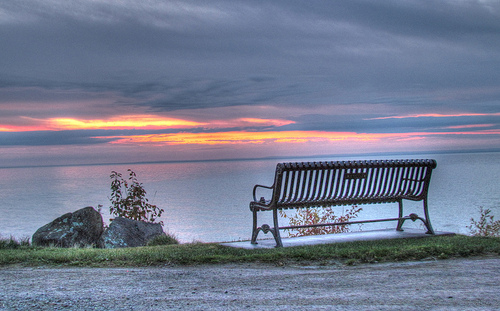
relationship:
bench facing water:
[251, 159, 438, 250] [2, 151, 497, 243]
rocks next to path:
[32, 206, 164, 251] [2, 253, 499, 310]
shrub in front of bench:
[279, 205, 364, 239] [251, 159, 438, 250]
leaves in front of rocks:
[95, 168, 165, 227] [32, 206, 164, 251]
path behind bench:
[2, 253, 499, 310] [251, 159, 438, 250]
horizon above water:
[1, 148, 499, 169] [2, 151, 497, 243]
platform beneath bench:
[220, 228, 455, 251] [251, 159, 438, 250]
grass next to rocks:
[3, 234, 180, 269] [32, 206, 164, 251]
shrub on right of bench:
[465, 207, 499, 237] [251, 159, 438, 250]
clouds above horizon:
[3, 2, 493, 146] [1, 148, 499, 169]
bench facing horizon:
[251, 159, 438, 250] [1, 148, 499, 169]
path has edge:
[2, 253, 499, 310] [2, 247, 499, 265]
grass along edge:
[3, 236, 500, 264] [2, 247, 499, 265]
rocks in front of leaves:
[32, 206, 164, 251] [95, 168, 165, 227]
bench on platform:
[251, 159, 438, 250] [220, 228, 455, 251]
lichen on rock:
[103, 223, 130, 249] [97, 216, 167, 250]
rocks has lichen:
[32, 206, 164, 251] [44, 217, 129, 251]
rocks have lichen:
[32, 206, 164, 251] [44, 217, 129, 251]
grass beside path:
[3, 234, 180, 269] [2, 253, 499, 310]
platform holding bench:
[220, 228, 455, 251] [251, 159, 438, 250]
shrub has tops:
[279, 205, 364, 239] [108, 168, 138, 182]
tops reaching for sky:
[108, 168, 138, 182] [0, 2, 497, 142]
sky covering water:
[0, 2, 497, 142] [2, 151, 497, 243]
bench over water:
[251, 159, 438, 250] [2, 151, 497, 243]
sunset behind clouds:
[0, 112, 498, 149] [3, 2, 493, 146]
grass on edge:
[3, 234, 180, 269] [2, 247, 499, 265]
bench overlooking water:
[251, 159, 438, 250] [2, 151, 497, 243]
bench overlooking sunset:
[251, 159, 438, 250] [0, 112, 498, 149]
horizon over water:
[1, 148, 499, 169] [2, 151, 497, 243]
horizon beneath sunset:
[1, 148, 499, 169] [0, 112, 498, 149]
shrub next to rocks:
[279, 205, 364, 239] [32, 206, 164, 251]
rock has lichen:
[97, 216, 167, 250] [103, 223, 130, 249]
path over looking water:
[2, 253, 499, 310] [2, 151, 497, 243]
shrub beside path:
[465, 207, 499, 237] [2, 253, 499, 310]